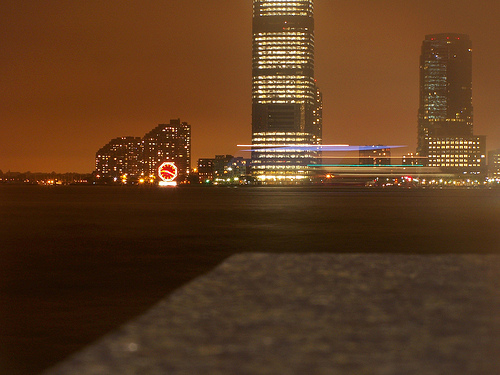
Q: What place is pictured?
A: It is a city.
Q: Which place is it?
A: It is a city.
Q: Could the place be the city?
A: Yes, it is the city.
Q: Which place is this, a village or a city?
A: It is a city.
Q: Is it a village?
A: No, it is a city.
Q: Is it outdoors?
A: Yes, it is outdoors.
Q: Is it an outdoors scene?
A: Yes, it is outdoors.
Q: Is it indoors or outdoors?
A: It is outdoors.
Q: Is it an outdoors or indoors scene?
A: It is outdoors.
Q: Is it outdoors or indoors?
A: It is outdoors.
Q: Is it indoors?
A: No, it is outdoors.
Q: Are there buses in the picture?
A: No, there are no buses.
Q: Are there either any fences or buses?
A: No, there are no buses or fences.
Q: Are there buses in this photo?
A: No, there are no buses.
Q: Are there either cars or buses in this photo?
A: No, there are no buses or cars.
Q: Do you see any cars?
A: No, there are no cars.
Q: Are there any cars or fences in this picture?
A: No, there are no cars or fences.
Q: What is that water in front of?
A: The water is in front of the city.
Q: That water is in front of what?
A: The water is in front of the city.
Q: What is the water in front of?
A: The water is in front of the city.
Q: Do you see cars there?
A: No, there are no cars.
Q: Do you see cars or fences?
A: No, there are no cars or fences.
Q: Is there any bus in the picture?
A: No, there are no buses.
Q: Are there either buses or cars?
A: No, there are no buses or cars.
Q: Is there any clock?
A: Yes, there is a clock.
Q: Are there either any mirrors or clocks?
A: Yes, there is a clock.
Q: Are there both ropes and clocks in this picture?
A: No, there is a clock but no ropes.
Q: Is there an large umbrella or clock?
A: Yes, there is a large clock.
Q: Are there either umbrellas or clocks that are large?
A: Yes, the clock is large.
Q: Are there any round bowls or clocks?
A: Yes, there is a round clock.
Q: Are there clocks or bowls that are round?
A: Yes, the clock is round.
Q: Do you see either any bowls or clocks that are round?
A: Yes, the clock is round.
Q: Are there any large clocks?
A: Yes, there is a large clock.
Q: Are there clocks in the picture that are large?
A: Yes, there is a large clock.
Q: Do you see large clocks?
A: Yes, there is a large clock.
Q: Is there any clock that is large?
A: Yes, there is a clock that is large.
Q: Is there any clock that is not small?
A: Yes, there is a large clock.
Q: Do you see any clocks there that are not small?
A: Yes, there is a large clock.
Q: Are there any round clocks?
A: Yes, there is a round clock.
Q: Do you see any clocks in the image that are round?
A: Yes, there is a clock that is round.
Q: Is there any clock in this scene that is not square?
A: Yes, there is a round clock.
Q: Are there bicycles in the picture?
A: No, there are no bicycles.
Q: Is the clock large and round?
A: Yes, the clock is large and round.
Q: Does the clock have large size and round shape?
A: Yes, the clock is large and round.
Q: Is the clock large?
A: Yes, the clock is large.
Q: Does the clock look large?
A: Yes, the clock is large.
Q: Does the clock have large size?
A: Yes, the clock is large.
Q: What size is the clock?
A: The clock is large.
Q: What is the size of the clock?
A: The clock is large.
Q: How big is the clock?
A: The clock is large.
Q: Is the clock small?
A: No, the clock is large.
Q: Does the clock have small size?
A: No, the clock is large.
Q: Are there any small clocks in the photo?
A: No, there is a clock but it is large.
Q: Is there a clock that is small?
A: No, there is a clock but it is large.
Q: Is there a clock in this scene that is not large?
A: No, there is a clock but it is large.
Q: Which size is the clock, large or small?
A: The clock is large.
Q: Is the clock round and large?
A: Yes, the clock is round and large.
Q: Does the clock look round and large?
A: Yes, the clock is round and large.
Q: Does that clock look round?
A: Yes, the clock is round.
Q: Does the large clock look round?
A: Yes, the clock is round.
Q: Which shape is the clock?
A: The clock is round.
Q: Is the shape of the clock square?
A: No, the clock is round.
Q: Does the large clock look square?
A: No, the clock is round.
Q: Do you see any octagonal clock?
A: No, there is a clock but it is round.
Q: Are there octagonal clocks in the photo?
A: No, there is a clock but it is round.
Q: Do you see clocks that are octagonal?
A: No, there is a clock but it is round.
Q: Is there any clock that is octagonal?
A: No, there is a clock but it is round.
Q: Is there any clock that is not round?
A: No, there is a clock but it is round.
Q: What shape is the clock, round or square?
A: The clock is round.